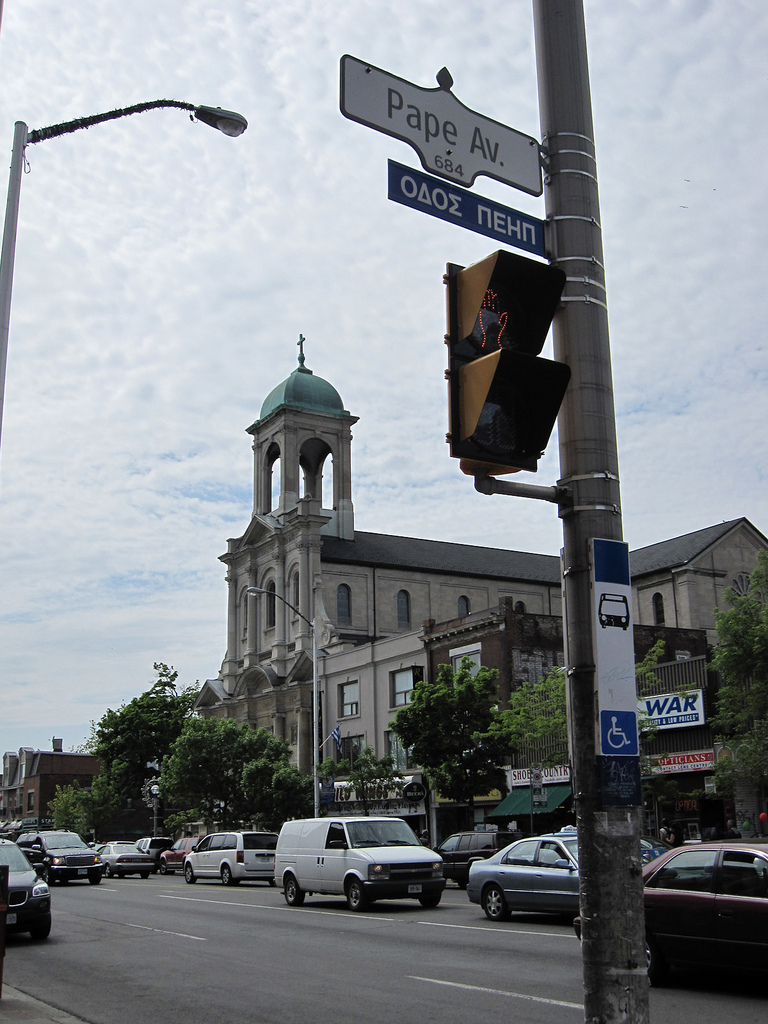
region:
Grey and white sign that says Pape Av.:
[341, 51, 543, 199]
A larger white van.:
[269, 816, 448, 910]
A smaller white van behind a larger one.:
[182, 830, 278, 889]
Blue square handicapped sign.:
[600, 708, 638, 757]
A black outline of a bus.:
[596, 592, 628, 630]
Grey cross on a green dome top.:
[294, 333, 307, 358]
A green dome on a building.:
[257, 369, 345, 419]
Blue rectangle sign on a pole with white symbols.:
[385, 159, 547, 257]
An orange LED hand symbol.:
[474, 287, 509, 350]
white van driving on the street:
[275, 815, 446, 910]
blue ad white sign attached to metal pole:
[586, 535, 638, 758]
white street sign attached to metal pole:
[339, 53, 546, 195]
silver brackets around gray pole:
[546, 164, 598, 188]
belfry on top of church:
[243, 329, 353, 536]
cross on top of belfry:
[291, 330, 308, 358]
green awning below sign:
[490, 783, 572, 821]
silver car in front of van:
[463, 829, 660, 931]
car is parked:
[427, 829, 515, 884]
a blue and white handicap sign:
[592, 705, 644, 760]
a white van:
[265, 807, 451, 916]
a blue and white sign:
[638, 682, 709, 736]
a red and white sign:
[643, 743, 720, 778]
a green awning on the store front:
[481, 779, 577, 826]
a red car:
[565, 835, 765, 997]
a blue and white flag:
[316, 720, 350, 758]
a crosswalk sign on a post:
[435, 243, 577, 482]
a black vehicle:
[7, 822, 105, 887]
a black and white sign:
[330, 44, 547, 196]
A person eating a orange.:
[358, 759, 475, 899]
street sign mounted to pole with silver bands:
[333, 49, 550, 258]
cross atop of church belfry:
[245, 333, 356, 531]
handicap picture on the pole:
[591, 703, 644, 757]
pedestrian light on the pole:
[450, 251, 559, 499]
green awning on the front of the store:
[486, 778, 573, 821]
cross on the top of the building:
[290, 330, 314, 363]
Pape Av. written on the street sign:
[381, 84, 515, 176]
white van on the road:
[274, 821, 447, 914]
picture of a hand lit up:
[478, 284, 513, 353]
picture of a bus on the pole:
[596, 587, 630, 628]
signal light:
[401, 258, 545, 470]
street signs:
[331, 54, 543, 236]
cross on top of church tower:
[285, 328, 315, 367]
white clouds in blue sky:
[89, 532, 128, 578]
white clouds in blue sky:
[37, 315, 126, 391]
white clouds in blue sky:
[89, 260, 178, 354]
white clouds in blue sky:
[243, 220, 315, 288]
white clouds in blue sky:
[612, 84, 708, 173]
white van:
[269, 817, 435, 902]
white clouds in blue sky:
[59, 361, 142, 475]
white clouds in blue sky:
[74, 552, 179, 646]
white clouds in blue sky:
[359, 315, 391, 354]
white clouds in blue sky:
[689, 236, 757, 308]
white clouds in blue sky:
[68, 183, 149, 253]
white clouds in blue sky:
[72, 36, 120, 68]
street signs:
[344, 67, 534, 251]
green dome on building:
[247, 350, 347, 415]